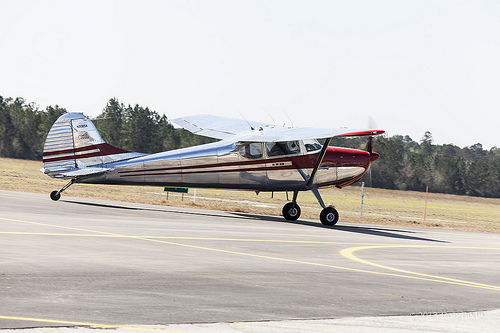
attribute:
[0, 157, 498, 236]
field — grassy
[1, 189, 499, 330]
runway — asphalt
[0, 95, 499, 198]
trees — in a line, distant, green, in a row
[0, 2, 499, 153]
sky — cloudy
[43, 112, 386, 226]
airplane — silver, red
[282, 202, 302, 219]
wheel — black, landing wheel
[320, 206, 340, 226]
wheel — black, landing wheel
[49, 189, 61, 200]
wheel — black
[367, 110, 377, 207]
propeller — moving, black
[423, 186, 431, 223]
post — orange, metal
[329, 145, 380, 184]
nose — red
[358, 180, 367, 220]
post — silver, fence post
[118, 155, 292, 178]
stripes — red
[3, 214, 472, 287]
line — yellow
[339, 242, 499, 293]
circle — yellow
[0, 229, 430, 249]
line — yellow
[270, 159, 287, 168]
writing — black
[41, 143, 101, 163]
stripes — red